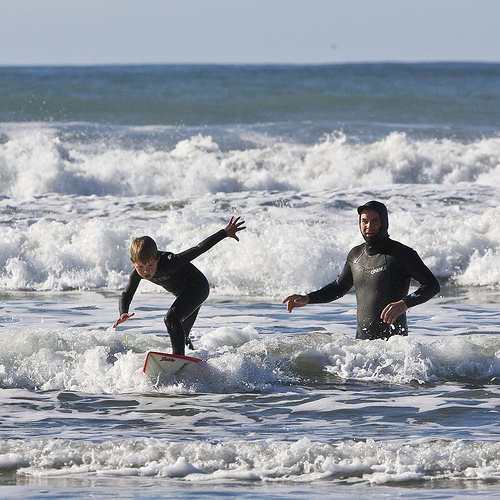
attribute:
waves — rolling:
[0, 120, 499, 499]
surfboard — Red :
[141, 351, 204, 377]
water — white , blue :
[4, 66, 496, 491]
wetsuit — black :
[306, 241, 439, 340]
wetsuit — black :
[125, 226, 228, 344]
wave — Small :
[8, 316, 485, 405]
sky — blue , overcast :
[2, 2, 499, 63]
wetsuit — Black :
[123, 219, 224, 343]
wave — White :
[8, 204, 498, 297]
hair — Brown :
[128, 236, 158, 264]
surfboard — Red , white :
[143, 351, 199, 376]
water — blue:
[243, 259, 343, 357]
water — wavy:
[226, 317, 278, 409]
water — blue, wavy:
[232, 134, 324, 402]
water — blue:
[74, 194, 492, 264]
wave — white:
[5, 395, 494, 500]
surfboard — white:
[134, 338, 204, 383]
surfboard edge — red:
[118, 343, 188, 379]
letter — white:
[364, 265, 374, 281]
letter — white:
[374, 268, 378, 273]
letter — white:
[376, 265, 378, 272]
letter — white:
[380, 264, 385, 278]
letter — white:
[374, 269, 382, 273]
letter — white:
[164, 274, 174, 293]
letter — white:
[163, 267, 171, 276]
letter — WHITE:
[160, 276, 169, 286]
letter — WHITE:
[164, 279, 173, 288]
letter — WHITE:
[156, 275, 166, 285]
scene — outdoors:
[7, 6, 484, 492]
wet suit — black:
[275, 196, 445, 340]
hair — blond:
[125, 236, 157, 265]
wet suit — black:
[112, 222, 220, 348]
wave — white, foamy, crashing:
[20, 129, 137, 212]